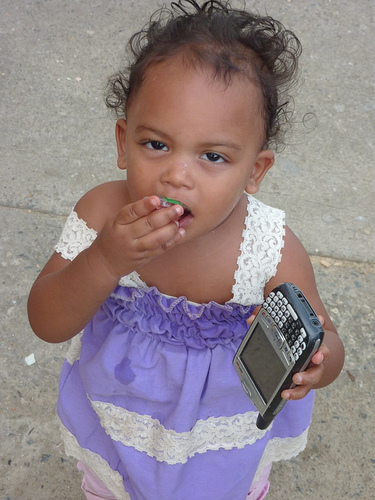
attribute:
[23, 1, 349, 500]
girl — eating, little, young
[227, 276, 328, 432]
phone — upside down, cell, black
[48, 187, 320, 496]
dress — purple, white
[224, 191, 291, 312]
lace — white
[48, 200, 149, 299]
strap — lace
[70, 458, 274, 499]
pants — pink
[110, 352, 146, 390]
spot — wet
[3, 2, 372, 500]
sidewalk — gray, cement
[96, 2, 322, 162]
hair — black, curly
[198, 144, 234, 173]
eye — dark brown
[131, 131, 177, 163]
eye — dark brown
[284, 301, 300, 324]
button — white